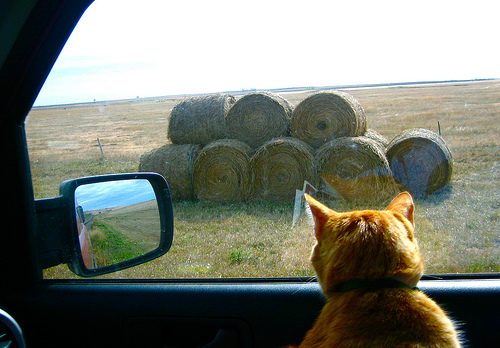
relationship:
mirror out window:
[61, 173, 174, 276] [28, 1, 499, 282]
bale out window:
[290, 90, 366, 149] [28, 1, 499, 282]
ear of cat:
[304, 191, 337, 242] [301, 192, 467, 346]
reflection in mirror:
[67, 195, 95, 267] [61, 173, 174, 276]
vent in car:
[1, 307, 23, 347] [0, 1, 498, 344]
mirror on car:
[61, 173, 174, 276] [0, 1, 498, 344]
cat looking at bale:
[301, 192, 467, 346] [290, 90, 366, 149]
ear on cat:
[304, 191, 337, 242] [301, 192, 467, 346]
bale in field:
[290, 90, 366, 149] [24, 80, 498, 277]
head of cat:
[299, 192, 423, 284] [301, 192, 467, 346]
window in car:
[28, 1, 499, 282] [0, 1, 498, 344]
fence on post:
[95, 136, 103, 154] [26, 135, 167, 165]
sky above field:
[36, 1, 496, 107] [24, 80, 498, 277]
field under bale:
[24, 80, 498, 277] [290, 90, 366, 149]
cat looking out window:
[301, 192, 467, 346] [28, 1, 499, 282]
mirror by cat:
[61, 173, 174, 276] [301, 192, 467, 346]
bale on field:
[290, 90, 366, 149] [24, 80, 498, 277]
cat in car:
[301, 192, 467, 346] [0, 1, 498, 344]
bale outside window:
[290, 90, 366, 149] [28, 1, 499, 282]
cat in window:
[301, 192, 467, 346] [28, 1, 499, 282]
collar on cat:
[330, 277, 415, 291] [301, 192, 467, 346]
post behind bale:
[26, 135, 167, 165] [290, 90, 366, 149]